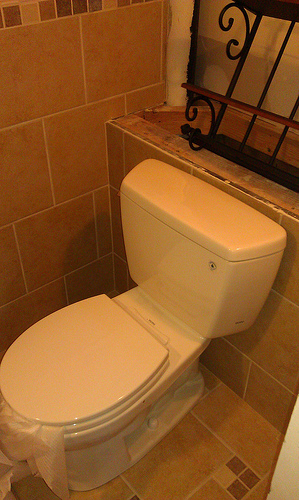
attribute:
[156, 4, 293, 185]
wall — exposed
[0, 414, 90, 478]
paper — white, hanging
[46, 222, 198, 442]
toilet — white, here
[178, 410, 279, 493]
tiles — brown, white, sectioned, ceramic, grouted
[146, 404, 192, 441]
bolt — covering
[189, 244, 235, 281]
logo — company, black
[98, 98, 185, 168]
drywall — broken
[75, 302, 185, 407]
lid — here, white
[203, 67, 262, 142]
rail — behind, black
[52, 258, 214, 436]
seat — protective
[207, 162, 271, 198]
rock — exposed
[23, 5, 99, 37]
tile — brown, patterned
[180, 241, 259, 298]
name — written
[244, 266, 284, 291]
handle — missing